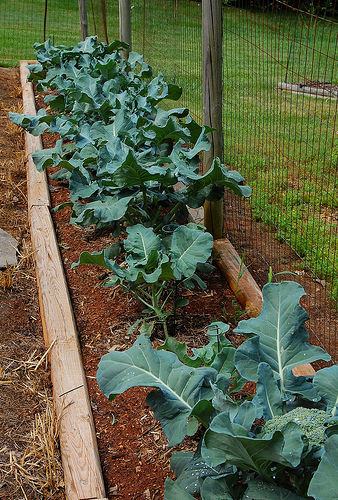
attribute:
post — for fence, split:
[198, 1, 229, 235]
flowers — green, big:
[30, 45, 223, 271]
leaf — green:
[231, 279, 334, 405]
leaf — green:
[95, 329, 236, 446]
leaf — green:
[203, 410, 309, 482]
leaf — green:
[168, 224, 214, 282]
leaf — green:
[122, 223, 164, 265]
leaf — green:
[67, 246, 125, 279]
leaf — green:
[175, 158, 254, 200]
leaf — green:
[75, 191, 137, 227]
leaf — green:
[110, 147, 178, 189]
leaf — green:
[96, 135, 141, 165]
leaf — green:
[175, 120, 218, 160]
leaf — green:
[30, 134, 77, 169]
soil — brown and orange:
[7, 137, 22, 162]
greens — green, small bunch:
[5, 35, 337, 329]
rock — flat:
[1, 225, 19, 273]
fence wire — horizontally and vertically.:
[2, 3, 337, 360]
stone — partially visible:
[0, 226, 31, 266]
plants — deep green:
[11, 26, 326, 492]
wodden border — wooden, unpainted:
[18, 57, 82, 353]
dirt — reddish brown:
[63, 234, 91, 293]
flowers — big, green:
[63, 110, 245, 307]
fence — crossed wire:
[3, 1, 337, 385]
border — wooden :
[45, 423, 87, 488]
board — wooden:
[197, 1, 229, 239]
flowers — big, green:
[92, 138, 158, 188]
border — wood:
[17, 50, 106, 488]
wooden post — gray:
[190, 7, 244, 247]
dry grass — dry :
[0, 347, 74, 499]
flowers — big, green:
[153, 355, 308, 452]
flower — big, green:
[82, 223, 210, 315]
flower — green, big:
[62, 120, 183, 208]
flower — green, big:
[74, 57, 148, 142]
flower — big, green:
[117, 174, 187, 283]